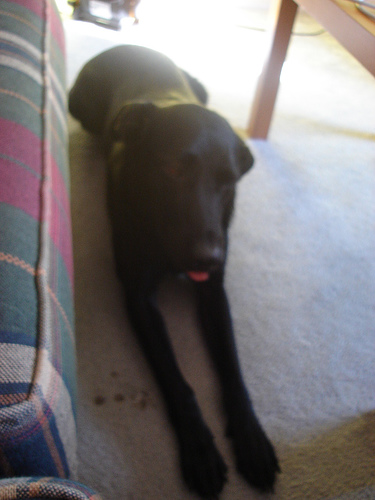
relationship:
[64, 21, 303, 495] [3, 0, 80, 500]
dog next to chair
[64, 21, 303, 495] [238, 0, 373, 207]
dog next to table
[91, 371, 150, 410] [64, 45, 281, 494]
stain next to dog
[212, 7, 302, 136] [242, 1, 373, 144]
cord of table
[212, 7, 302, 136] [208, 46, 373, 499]
cord on carpet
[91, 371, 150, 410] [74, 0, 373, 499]
stain on carpet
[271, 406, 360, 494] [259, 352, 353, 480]
trim on carpet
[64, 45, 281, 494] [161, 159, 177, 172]
dog has left eye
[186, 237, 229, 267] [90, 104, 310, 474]
nose on dog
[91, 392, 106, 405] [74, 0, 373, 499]
stain on a carpet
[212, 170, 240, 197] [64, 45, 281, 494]
eye on dog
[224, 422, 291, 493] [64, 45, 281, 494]
paw on dog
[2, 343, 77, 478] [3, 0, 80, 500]
stripe on chair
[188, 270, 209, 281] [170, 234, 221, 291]
tongue in mouth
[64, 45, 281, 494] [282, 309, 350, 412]
dog lying on carpet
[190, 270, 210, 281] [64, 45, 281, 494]
tongue of dog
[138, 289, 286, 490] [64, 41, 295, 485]
legs of dogs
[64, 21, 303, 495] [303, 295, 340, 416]
dog laying on carpet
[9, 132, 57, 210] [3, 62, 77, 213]
stripe on chair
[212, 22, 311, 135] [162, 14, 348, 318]
cord on floor